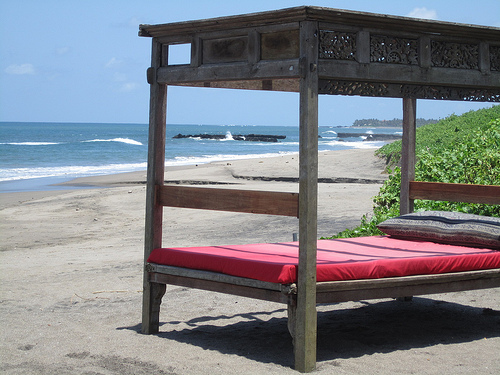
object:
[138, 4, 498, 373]
bed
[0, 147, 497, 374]
beach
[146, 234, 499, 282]
mattress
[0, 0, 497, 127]
sky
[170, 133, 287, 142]
rocks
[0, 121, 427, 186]
ocean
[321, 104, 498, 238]
hill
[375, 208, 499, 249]
pillow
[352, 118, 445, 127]
tree line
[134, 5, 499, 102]
canopy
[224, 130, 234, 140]
waves